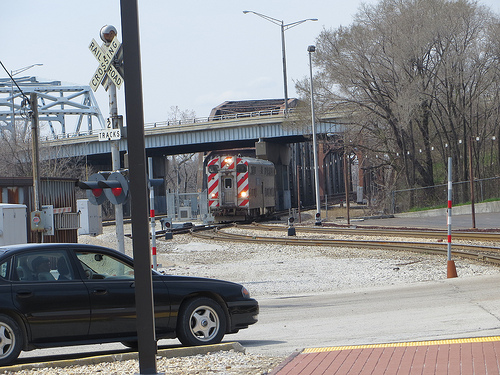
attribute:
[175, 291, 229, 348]
tire — right front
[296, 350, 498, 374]
brick — red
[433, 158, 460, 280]
pole — gray, white, red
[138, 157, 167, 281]
pole — red, white, gray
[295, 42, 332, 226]
pole — red, white, gray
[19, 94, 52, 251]
pole — red, white, gray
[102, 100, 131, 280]
pole — red, white, gray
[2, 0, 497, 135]
sky — pretty, calm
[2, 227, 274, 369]
car — black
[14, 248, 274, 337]
sedan — black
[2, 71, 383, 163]
bridge — green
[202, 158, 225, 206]
stripes — white, red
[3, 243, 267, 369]
car — black